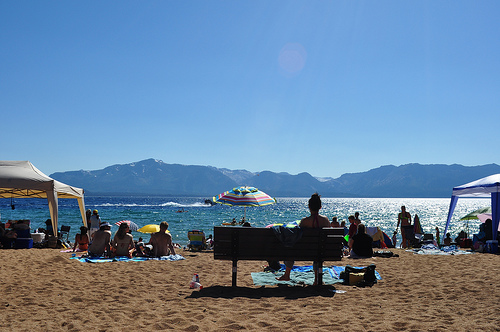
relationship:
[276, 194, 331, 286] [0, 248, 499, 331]
woman on beach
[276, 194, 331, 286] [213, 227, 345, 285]
woman sitting on bench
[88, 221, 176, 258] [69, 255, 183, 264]
people on towel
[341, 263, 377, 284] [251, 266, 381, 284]
bag sitting on towel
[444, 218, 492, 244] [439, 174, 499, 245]
people under canopy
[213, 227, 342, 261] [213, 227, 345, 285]
back on bench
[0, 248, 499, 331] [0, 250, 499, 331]
beach has footprints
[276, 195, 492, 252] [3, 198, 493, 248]
sun glistening on water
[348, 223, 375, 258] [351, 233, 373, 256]
woman wearing a shirt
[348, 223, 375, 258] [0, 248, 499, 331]
woman sitting on beach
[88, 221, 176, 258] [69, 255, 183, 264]
people sitting on towel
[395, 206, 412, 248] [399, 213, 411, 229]
woman wearing a bikini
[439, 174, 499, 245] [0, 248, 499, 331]
canopy on beach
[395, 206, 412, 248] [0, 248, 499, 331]
woman on beach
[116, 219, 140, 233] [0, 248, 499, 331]
umbrella on beach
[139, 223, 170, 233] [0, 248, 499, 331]
umbrella on beach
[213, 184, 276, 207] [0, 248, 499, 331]
beach umbrella on beach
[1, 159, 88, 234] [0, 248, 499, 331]
canopy on beach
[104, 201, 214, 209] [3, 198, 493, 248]
wave in water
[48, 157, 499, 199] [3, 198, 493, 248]
mountains beside water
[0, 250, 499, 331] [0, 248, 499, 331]
footprints on beach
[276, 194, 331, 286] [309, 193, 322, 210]
woman has hair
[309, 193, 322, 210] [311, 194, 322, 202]
hair in a bun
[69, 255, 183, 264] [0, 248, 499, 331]
towel on beach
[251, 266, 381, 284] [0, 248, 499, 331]
towel on beach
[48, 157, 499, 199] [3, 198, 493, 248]
mountains across water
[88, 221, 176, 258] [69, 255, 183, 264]
people are sitting on towel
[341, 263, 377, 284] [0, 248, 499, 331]
bag sitting on beach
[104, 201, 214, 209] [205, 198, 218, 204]
wave coming from boat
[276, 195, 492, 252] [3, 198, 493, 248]
sun on water